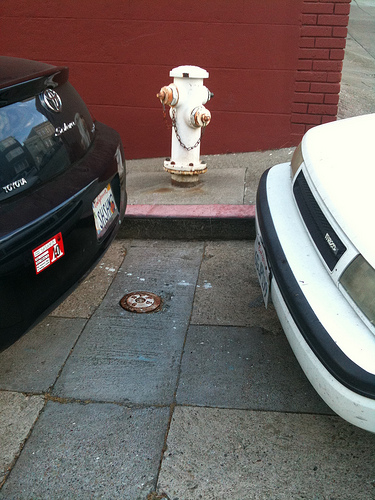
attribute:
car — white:
[320, 129, 351, 176]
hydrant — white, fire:
[155, 62, 212, 187]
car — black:
[1, 53, 127, 354]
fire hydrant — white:
[157, 61, 214, 187]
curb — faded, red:
[114, 144, 296, 241]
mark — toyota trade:
[1, 183, 20, 198]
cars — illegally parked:
[238, 105, 373, 403]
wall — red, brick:
[1, 1, 349, 160]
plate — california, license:
[90, 183, 121, 240]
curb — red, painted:
[101, 151, 277, 250]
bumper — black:
[256, 166, 373, 399]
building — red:
[1, 5, 353, 179]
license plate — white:
[82, 190, 122, 233]